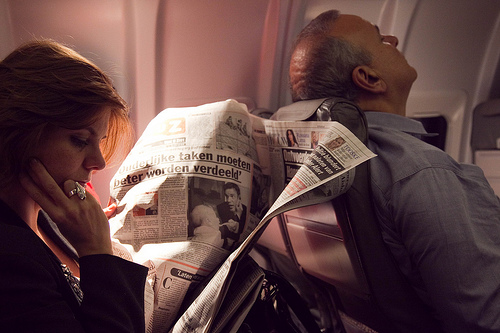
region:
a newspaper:
[134, 119, 341, 199]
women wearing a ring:
[71, 183, 97, 198]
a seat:
[355, 190, 374, 261]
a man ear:
[351, 61, 391, 91]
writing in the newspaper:
[168, 150, 247, 177]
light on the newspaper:
[125, 149, 172, 181]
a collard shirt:
[382, 115, 415, 128]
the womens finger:
[21, 170, 58, 194]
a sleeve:
[75, 261, 143, 312]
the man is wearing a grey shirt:
[378, 145, 450, 220]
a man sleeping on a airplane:
[245, 12, 499, 326]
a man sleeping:
[278, 23, 482, 318]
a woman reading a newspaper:
[7, 44, 382, 318]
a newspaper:
[89, 63, 403, 331]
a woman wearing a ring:
[6, 43, 138, 295]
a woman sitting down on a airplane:
[11, 44, 347, 329]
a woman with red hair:
[7, 32, 132, 212]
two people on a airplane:
[22, 13, 493, 330]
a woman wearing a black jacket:
[0, 45, 141, 321]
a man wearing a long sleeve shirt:
[290, 28, 491, 328]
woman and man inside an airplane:
[2, 3, 497, 327]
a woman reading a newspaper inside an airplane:
[2, 35, 363, 330]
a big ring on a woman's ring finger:
[62, 170, 87, 206]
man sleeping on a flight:
[287, 1, 499, 207]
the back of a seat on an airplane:
[286, 209, 372, 290]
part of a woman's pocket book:
[247, 266, 323, 330]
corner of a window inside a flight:
[422, 43, 488, 149]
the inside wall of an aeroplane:
[110, 1, 279, 94]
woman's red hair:
[3, 26, 138, 186]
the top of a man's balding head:
[272, 16, 361, 101]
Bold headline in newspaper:
[112, 151, 269, 248]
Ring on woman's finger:
[68, 182, 87, 199]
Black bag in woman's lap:
[260, 242, 345, 332]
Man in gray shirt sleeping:
[286, 35, 498, 331]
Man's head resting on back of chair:
[286, 35, 419, 111]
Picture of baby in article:
[190, 205, 224, 247]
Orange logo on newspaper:
[162, 115, 187, 135]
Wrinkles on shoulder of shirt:
[369, 150, 499, 224]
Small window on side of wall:
[406, 89, 460, 156]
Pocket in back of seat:
[283, 213, 373, 297]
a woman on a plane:
[10, 23, 301, 325]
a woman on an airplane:
[7, 23, 284, 330]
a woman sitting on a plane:
[22, 23, 258, 285]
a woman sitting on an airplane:
[28, 20, 318, 332]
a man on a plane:
[279, 16, 494, 204]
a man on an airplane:
[251, 8, 492, 229]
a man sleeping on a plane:
[240, 7, 468, 251]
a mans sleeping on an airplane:
[259, 8, 482, 276]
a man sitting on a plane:
[284, 16, 493, 253]